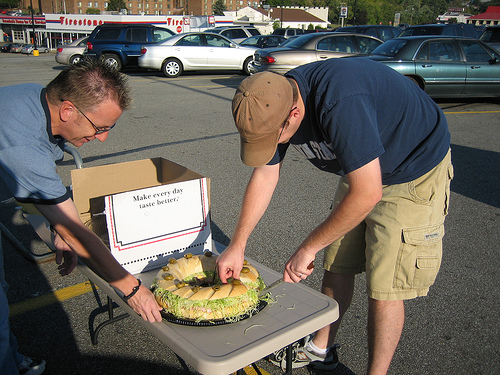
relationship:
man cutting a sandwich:
[215, 56, 455, 373] [149, 252, 267, 323]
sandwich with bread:
[149, 252, 267, 323] [152, 251, 259, 320]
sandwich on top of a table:
[149, 252, 267, 323] [22, 187, 341, 373]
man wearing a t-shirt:
[215, 56, 455, 373] [257, 56, 451, 184]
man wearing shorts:
[215, 56, 455, 373] [322, 147, 454, 300]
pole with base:
[30, 0, 40, 58] [31, 50, 40, 57]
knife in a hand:
[261, 260, 316, 296] [282, 249, 316, 283]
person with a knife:
[215, 56, 455, 373] [261, 260, 316, 296]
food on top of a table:
[149, 252, 267, 323] [22, 187, 341, 373]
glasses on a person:
[59, 94, 118, 136] [1, 58, 164, 374]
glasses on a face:
[59, 94, 118, 136] [64, 101, 122, 150]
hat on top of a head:
[227, 69, 296, 168] [234, 70, 305, 148]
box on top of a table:
[66, 157, 212, 276] [22, 187, 341, 373]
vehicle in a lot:
[340, 36, 499, 104] [0, 51, 499, 374]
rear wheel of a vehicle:
[102, 55, 124, 76] [83, 25, 177, 71]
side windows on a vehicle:
[411, 37, 498, 63] [340, 36, 499, 104]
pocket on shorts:
[393, 224, 447, 291] [322, 147, 454, 300]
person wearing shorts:
[215, 56, 455, 373] [322, 147, 454, 300]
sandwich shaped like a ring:
[149, 252, 267, 323] [298, 272, 303, 280]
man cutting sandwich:
[215, 56, 455, 373] [149, 252, 267, 323]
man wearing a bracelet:
[1, 58, 164, 374] [121, 280, 148, 303]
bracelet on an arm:
[121, 280, 148, 303] [13, 146, 166, 322]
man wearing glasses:
[1, 58, 164, 374] [59, 94, 118, 136]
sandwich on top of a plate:
[149, 252, 267, 323] [146, 278, 290, 327]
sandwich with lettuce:
[149, 252, 267, 323] [152, 277, 270, 323]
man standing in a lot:
[215, 56, 455, 373] [0, 51, 499, 374]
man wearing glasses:
[215, 56, 455, 373] [272, 106, 303, 142]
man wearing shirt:
[215, 56, 455, 373] [257, 56, 451, 184]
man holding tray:
[1, 58, 164, 374] [146, 278, 290, 327]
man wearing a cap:
[215, 56, 455, 373] [227, 69, 296, 168]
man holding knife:
[215, 56, 455, 373] [261, 260, 316, 296]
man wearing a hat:
[215, 56, 455, 373] [227, 69, 296, 168]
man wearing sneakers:
[215, 56, 455, 373] [267, 336, 346, 371]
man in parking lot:
[215, 56, 455, 373] [0, 51, 499, 374]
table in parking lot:
[22, 187, 341, 373] [0, 51, 499, 374]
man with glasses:
[1, 58, 164, 374] [59, 94, 118, 136]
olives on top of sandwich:
[160, 249, 249, 290] [149, 252, 267, 323]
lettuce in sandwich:
[152, 277, 270, 323] [149, 252, 267, 323]